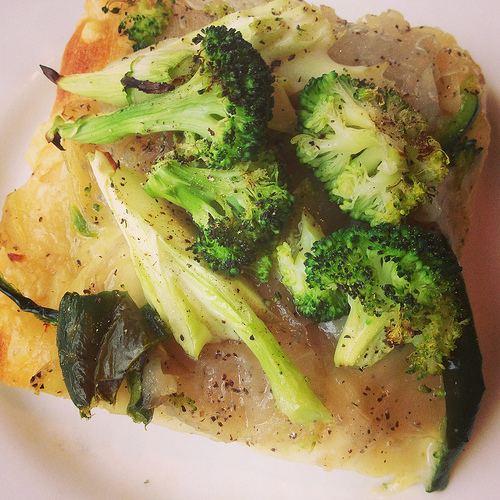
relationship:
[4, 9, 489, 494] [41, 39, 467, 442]
plate under food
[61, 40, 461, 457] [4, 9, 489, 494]
vegetables on plate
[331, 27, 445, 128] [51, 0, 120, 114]
meat topping bread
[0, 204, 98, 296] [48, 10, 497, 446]
cheese on meat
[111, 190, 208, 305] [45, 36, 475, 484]
spinach on toast